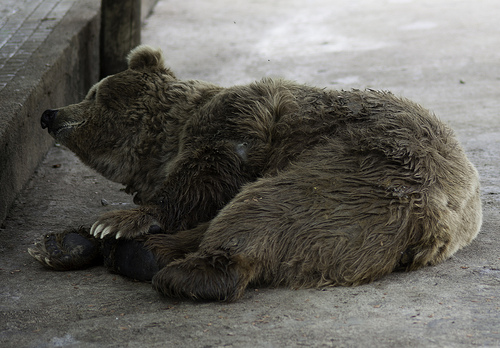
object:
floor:
[0, 1, 102, 227]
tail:
[404, 188, 484, 269]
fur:
[277, 152, 423, 227]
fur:
[179, 86, 389, 167]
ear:
[126, 42, 165, 73]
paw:
[26, 227, 99, 269]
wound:
[233, 132, 252, 163]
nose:
[40, 108, 56, 129]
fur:
[292, 193, 362, 242]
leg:
[196, 158, 395, 289]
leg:
[160, 217, 217, 264]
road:
[0, 0, 499, 346]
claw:
[115, 231, 122, 240]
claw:
[100, 225, 114, 240]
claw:
[89, 220, 100, 235]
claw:
[93, 220, 104, 237]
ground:
[0, 0, 498, 346]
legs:
[138, 147, 259, 231]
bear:
[25, 43, 485, 303]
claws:
[86, 217, 124, 241]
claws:
[27, 237, 56, 267]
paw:
[84, 213, 144, 242]